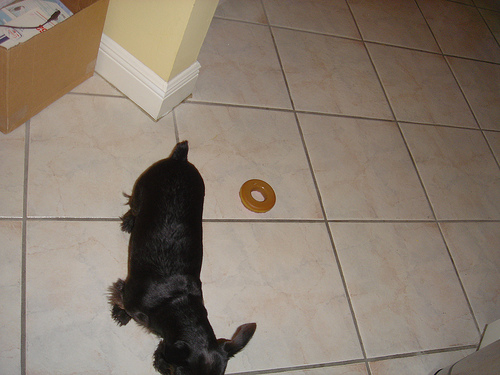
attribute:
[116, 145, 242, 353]
dog — black, small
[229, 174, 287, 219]
toy — brown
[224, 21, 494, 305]
floor — white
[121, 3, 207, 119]
wall — yellow, tan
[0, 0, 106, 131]
box — brown